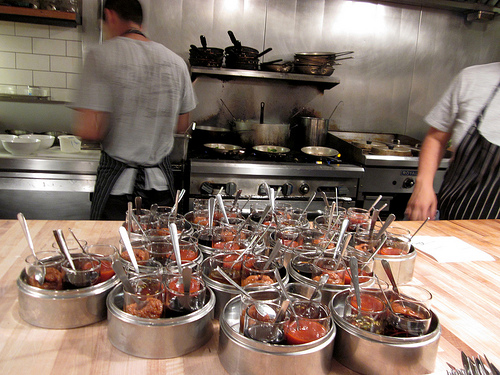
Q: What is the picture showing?
A: It is showing a kitchen.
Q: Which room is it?
A: It is a kitchen.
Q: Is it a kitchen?
A: Yes, it is a kitchen.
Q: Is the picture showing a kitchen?
A: Yes, it is showing a kitchen.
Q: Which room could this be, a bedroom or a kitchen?
A: It is a kitchen.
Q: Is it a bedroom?
A: No, it is a kitchen.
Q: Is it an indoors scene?
A: Yes, it is indoors.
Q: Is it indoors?
A: Yes, it is indoors.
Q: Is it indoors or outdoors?
A: It is indoors.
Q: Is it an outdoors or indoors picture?
A: It is indoors.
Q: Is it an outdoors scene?
A: No, it is indoors.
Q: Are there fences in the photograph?
A: No, there are no fences.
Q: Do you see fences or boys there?
A: No, there are no fences or boys.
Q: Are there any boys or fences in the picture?
A: No, there are no fences or boys.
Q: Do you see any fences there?
A: No, there are no fences.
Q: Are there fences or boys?
A: No, there are no fences or boys.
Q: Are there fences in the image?
A: No, there are no fences.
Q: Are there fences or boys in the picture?
A: No, there are no fences or boys.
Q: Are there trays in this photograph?
A: No, there are no trays.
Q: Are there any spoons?
A: Yes, there is a spoon.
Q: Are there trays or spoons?
A: Yes, there is a spoon.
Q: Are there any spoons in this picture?
A: Yes, there is a spoon.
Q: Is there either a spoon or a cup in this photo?
A: Yes, there is a spoon.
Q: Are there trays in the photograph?
A: No, there are no trays.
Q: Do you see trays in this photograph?
A: No, there are no trays.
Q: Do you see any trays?
A: No, there are no trays.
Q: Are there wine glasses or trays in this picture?
A: No, there are no trays or wine glasses.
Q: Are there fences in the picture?
A: No, there are no fences.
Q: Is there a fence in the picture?
A: No, there are no fences.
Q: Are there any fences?
A: No, there are no fences.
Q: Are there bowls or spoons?
A: Yes, there is a spoon.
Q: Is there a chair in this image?
A: No, there are no chairs.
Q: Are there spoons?
A: Yes, there is a spoon.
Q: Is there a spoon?
A: Yes, there is a spoon.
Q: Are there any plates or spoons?
A: Yes, there is a spoon.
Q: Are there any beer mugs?
A: No, there are no beer mugs.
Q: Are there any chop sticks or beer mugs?
A: No, there are no beer mugs or chop sticks.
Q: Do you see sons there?
A: No, there are no sons.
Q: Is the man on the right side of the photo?
A: Yes, the man is on the right of the image.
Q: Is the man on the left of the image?
A: No, the man is on the right of the image.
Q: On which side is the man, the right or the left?
A: The man is on the right of the image.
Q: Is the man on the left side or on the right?
A: The man is on the right of the image.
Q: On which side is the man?
A: The man is on the right of the image.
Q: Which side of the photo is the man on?
A: The man is on the right of the image.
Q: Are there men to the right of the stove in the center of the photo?
A: Yes, there is a man to the right of the stove.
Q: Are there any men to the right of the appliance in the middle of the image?
A: Yes, there is a man to the right of the stove.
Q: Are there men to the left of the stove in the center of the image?
A: No, the man is to the right of the stove.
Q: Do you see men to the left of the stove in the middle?
A: No, the man is to the right of the stove.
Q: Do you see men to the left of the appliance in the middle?
A: No, the man is to the right of the stove.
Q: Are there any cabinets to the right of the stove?
A: No, there is a man to the right of the stove.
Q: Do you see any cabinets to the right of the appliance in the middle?
A: No, there is a man to the right of the stove.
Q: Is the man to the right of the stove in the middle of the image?
A: Yes, the man is to the right of the stove.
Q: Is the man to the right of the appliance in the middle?
A: Yes, the man is to the right of the stove.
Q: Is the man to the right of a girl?
A: No, the man is to the right of the stove.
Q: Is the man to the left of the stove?
A: No, the man is to the right of the stove.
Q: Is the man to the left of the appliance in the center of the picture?
A: No, the man is to the right of the stove.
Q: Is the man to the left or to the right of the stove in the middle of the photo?
A: The man is to the right of the stove.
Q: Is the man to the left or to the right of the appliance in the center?
A: The man is to the right of the stove.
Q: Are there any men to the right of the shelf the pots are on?
A: Yes, there is a man to the right of the shelf.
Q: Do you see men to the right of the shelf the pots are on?
A: Yes, there is a man to the right of the shelf.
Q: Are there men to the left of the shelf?
A: No, the man is to the right of the shelf.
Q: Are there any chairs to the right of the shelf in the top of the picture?
A: No, there is a man to the right of the shelf.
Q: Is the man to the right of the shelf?
A: Yes, the man is to the right of the shelf.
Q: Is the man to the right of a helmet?
A: No, the man is to the right of the shelf.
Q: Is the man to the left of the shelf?
A: No, the man is to the right of the shelf.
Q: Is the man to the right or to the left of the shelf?
A: The man is to the right of the shelf.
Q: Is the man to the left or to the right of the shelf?
A: The man is to the right of the shelf.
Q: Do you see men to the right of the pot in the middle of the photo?
A: Yes, there is a man to the right of the pot.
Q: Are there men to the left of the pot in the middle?
A: No, the man is to the right of the pot.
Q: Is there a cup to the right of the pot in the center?
A: No, there is a man to the right of the pot.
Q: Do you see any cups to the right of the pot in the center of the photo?
A: No, there is a man to the right of the pot.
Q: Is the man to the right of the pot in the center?
A: Yes, the man is to the right of the pot.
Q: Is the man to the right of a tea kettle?
A: No, the man is to the right of the pot.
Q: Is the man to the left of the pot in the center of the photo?
A: No, the man is to the right of the pot.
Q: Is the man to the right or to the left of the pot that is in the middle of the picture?
A: The man is to the right of the pot.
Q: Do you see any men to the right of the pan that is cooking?
A: Yes, there is a man to the right of the pan.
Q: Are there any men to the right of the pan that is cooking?
A: Yes, there is a man to the right of the pan.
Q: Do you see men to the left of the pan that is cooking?
A: No, the man is to the right of the pan.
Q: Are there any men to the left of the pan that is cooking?
A: No, the man is to the right of the pan.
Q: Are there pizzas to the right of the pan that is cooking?
A: No, there is a man to the right of the pan.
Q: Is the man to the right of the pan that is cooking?
A: Yes, the man is to the right of the pan.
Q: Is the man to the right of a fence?
A: No, the man is to the right of the pan.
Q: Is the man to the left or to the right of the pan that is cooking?
A: The man is to the right of the pan.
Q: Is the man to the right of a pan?
A: Yes, the man is to the right of a pan.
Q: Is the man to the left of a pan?
A: No, the man is to the right of a pan.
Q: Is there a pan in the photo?
A: Yes, there is a pan.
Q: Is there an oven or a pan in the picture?
A: Yes, there is a pan.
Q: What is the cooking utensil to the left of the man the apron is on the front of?
A: The cooking utensil is a pan.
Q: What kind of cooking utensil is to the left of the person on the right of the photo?
A: The cooking utensil is a pan.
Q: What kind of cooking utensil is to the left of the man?
A: The cooking utensil is a pan.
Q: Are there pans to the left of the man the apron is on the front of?
A: Yes, there is a pan to the left of the man.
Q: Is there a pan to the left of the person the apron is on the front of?
A: Yes, there is a pan to the left of the man.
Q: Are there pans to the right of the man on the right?
A: No, the pan is to the left of the man.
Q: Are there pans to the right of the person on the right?
A: No, the pan is to the left of the man.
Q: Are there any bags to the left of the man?
A: No, there is a pan to the left of the man.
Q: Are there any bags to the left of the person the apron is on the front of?
A: No, there is a pan to the left of the man.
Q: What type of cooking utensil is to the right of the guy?
A: The cooking utensil is a pan.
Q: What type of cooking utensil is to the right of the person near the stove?
A: The cooking utensil is a pan.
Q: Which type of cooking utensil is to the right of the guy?
A: The cooking utensil is a pan.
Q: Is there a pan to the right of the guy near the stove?
A: Yes, there is a pan to the right of the guy.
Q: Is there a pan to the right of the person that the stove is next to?
A: Yes, there is a pan to the right of the guy.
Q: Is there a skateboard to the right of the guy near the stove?
A: No, there is a pan to the right of the guy.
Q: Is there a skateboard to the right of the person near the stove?
A: No, there is a pan to the right of the guy.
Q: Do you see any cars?
A: No, there are no cars.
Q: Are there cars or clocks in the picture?
A: No, there are no cars or clocks.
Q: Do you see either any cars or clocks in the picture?
A: No, there are no cars or clocks.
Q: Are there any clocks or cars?
A: No, there are no cars or clocks.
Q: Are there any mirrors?
A: No, there are no mirrors.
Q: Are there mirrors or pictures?
A: No, there are no mirrors or pictures.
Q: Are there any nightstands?
A: No, there are no nightstands.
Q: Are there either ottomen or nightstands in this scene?
A: No, there are no nightstands or ottomen.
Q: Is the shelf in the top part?
A: Yes, the shelf is in the top of the image.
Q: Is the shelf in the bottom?
A: No, the shelf is in the top of the image.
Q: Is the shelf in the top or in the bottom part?
A: The shelf is in the top of the image.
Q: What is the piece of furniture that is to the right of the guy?
A: The piece of furniture is a shelf.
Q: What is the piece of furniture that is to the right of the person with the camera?
A: The piece of furniture is a shelf.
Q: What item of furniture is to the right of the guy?
A: The piece of furniture is a shelf.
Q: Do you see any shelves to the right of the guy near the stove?
A: Yes, there is a shelf to the right of the guy.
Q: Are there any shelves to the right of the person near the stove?
A: Yes, there is a shelf to the right of the guy.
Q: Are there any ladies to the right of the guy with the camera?
A: No, there is a shelf to the right of the guy.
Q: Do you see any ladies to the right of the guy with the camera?
A: No, there is a shelf to the right of the guy.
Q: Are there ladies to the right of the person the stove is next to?
A: No, there is a shelf to the right of the guy.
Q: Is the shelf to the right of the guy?
A: Yes, the shelf is to the right of the guy.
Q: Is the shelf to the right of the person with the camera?
A: Yes, the shelf is to the right of the guy.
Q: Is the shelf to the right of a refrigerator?
A: No, the shelf is to the right of the guy.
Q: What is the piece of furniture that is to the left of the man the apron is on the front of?
A: The piece of furniture is a shelf.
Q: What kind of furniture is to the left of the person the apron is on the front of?
A: The piece of furniture is a shelf.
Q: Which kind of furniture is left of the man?
A: The piece of furniture is a shelf.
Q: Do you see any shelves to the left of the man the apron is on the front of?
A: Yes, there is a shelf to the left of the man.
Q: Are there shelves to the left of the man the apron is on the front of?
A: Yes, there is a shelf to the left of the man.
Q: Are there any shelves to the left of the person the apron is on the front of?
A: Yes, there is a shelf to the left of the man.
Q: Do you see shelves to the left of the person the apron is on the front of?
A: Yes, there is a shelf to the left of the man.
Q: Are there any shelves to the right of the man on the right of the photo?
A: No, the shelf is to the left of the man.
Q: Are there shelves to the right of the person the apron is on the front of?
A: No, the shelf is to the left of the man.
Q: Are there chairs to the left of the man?
A: No, there is a shelf to the left of the man.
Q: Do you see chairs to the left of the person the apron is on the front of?
A: No, there is a shelf to the left of the man.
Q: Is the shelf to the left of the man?
A: Yes, the shelf is to the left of the man.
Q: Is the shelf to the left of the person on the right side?
A: Yes, the shelf is to the left of the man.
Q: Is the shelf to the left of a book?
A: No, the shelf is to the left of the man.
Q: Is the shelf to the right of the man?
A: No, the shelf is to the left of the man.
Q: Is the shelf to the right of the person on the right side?
A: No, the shelf is to the left of the man.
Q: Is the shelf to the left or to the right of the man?
A: The shelf is to the left of the man.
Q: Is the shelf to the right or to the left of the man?
A: The shelf is to the left of the man.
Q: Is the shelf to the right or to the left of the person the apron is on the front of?
A: The shelf is to the left of the man.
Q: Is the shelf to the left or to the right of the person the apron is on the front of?
A: The shelf is to the left of the man.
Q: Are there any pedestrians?
A: No, there are no pedestrians.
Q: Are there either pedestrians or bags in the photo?
A: No, there are no pedestrians or bags.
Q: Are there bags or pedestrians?
A: No, there are no pedestrians or bags.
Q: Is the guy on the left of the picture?
A: Yes, the guy is on the left of the image.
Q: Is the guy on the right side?
A: No, the guy is on the left of the image.